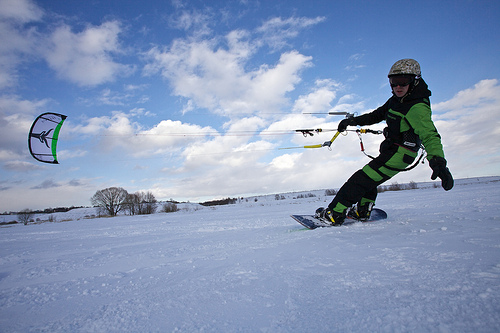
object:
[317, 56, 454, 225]
person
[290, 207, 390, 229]
snowboard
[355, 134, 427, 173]
rope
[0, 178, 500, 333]
snow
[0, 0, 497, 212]
sky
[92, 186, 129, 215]
tree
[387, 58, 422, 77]
helmet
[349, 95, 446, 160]
jacket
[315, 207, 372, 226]
shoes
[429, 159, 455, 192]
glove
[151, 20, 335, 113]
clouds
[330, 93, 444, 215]
outfit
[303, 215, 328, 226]
snow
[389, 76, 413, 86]
goggles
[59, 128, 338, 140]
strings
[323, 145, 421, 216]
leg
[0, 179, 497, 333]
ground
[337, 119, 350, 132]
hand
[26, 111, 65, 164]
parasail